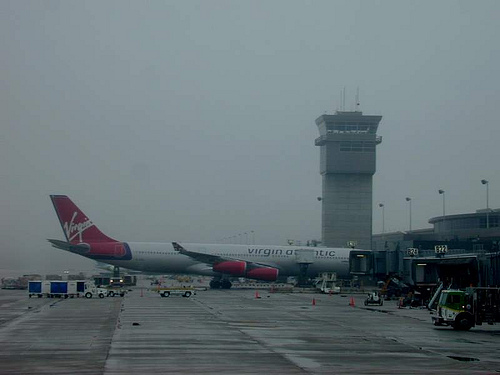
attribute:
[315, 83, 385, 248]
tower — concrete, silver, tall, gray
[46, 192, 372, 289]
plane — parked, virgin atlantic, white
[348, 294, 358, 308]
cone — orange, small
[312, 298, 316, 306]
cone — small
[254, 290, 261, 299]
cone — orange, small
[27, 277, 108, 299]
truck — white, large, blue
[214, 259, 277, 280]
engine — red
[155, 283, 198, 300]
vehicle — small, yellow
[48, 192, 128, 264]
tail — red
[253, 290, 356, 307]
cones — orange, cement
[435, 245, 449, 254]
numbers — black, white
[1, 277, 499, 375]
ground — cement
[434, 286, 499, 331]
truck — green, white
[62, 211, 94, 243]
lettering — white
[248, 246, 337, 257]
lettering — black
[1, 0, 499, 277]
overcast — day